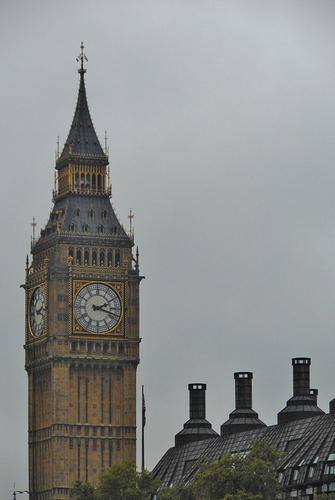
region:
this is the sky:
[162, 45, 296, 261]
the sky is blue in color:
[195, 70, 284, 215]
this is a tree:
[209, 430, 265, 497]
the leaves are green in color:
[208, 476, 242, 491]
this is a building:
[57, 208, 126, 497]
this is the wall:
[82, 397, 116, 427]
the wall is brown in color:
[74, 371, 114, 405]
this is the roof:
[193, 425, 229, 445]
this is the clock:
[75, 288, 117, 343]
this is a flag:
[138, 377, 155, 428]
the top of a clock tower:
[36, 26, 155, 219]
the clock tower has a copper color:
[26, 162, 159, 407]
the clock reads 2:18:
[51, 268, 141, 351]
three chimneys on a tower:
[174, 341, 325, 469]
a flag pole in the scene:
[135, 380, 157, 473]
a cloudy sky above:
[146, 121, 312, 251]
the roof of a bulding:
[157, 441, 328, 497]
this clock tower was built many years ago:
[27, 205, 324, 450]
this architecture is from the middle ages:
[27, 227, 324, 478]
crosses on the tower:
[20, 199, 152, 250]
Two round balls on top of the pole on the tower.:
[79, 40, 84, 48]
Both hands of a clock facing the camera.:
[91, 301, 119, 318]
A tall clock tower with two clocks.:
[24, 35, 143, 498]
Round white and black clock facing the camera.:
[72, 282, 120, 333]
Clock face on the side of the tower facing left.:
[28, 286, 47, 336]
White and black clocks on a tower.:
[24, 284, 123, 335]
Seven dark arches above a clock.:
[68, 246, 121, 267]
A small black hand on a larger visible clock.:
[90, 301, 109, 310]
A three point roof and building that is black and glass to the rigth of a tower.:
[143, 357, 333, 498]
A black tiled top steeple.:
[56, 74, 111, 161]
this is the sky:
[159, 18, 284, 178]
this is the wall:
[16, 158, 153, 442]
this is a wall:
[69, 380, 109, 437]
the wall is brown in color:
[69, 381, 107, 418]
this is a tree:
[206, 456, 233, 477]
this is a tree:
[117, 466, 136, 498]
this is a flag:
[138, 385, 160, 460]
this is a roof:
[176, 412, 247, 457]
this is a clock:
[72, 285, 126, 325]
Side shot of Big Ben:
[18, 40, 145, 498]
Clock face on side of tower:
[70, 279, 126, 336]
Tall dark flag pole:
[140, 383, 147, 481]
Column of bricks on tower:
[51, 360, 69, 421]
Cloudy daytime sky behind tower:
[0, 0, 333, 497]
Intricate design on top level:
[70, 162, 106, 194]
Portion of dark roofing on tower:
[49, 73, 112, 162]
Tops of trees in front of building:
[67, 438, 292, 498]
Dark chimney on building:
[172, 381, 219, 444]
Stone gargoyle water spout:
[138, 274, 145, 283]